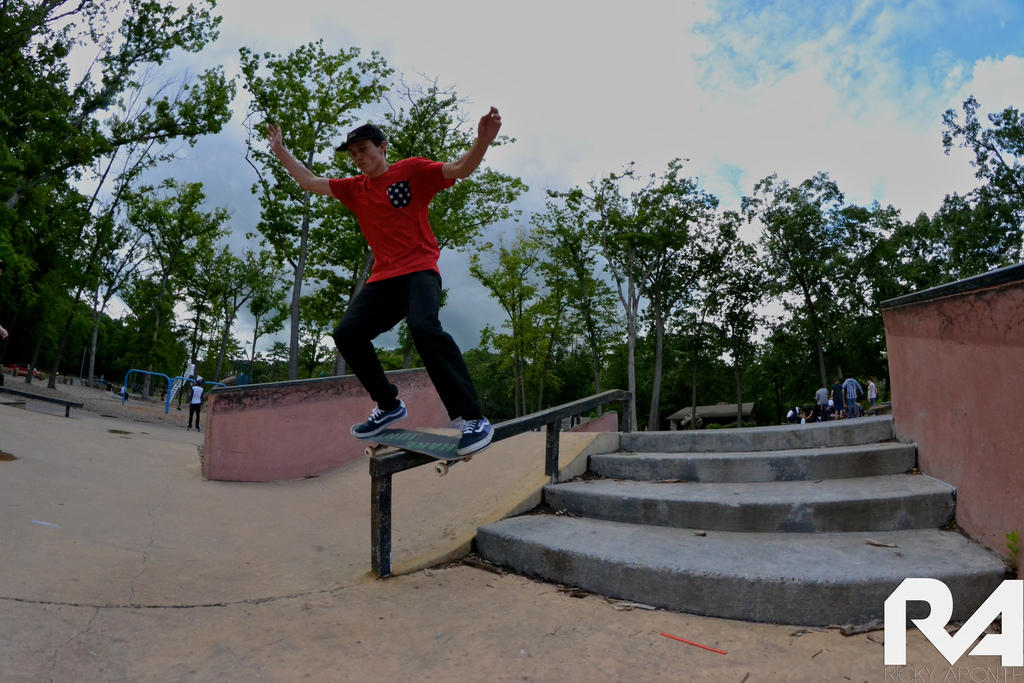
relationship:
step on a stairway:
[467, 501, 1021, 632] [462, 398, 998, 641]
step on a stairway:
[530, 463, 968, 536] [462, 398, 998, 641]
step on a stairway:
[582, 435, 925, 483] [462, 398, 998, 641]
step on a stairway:
[612, 416, 898, 448] [486, 424, 1022, 636]